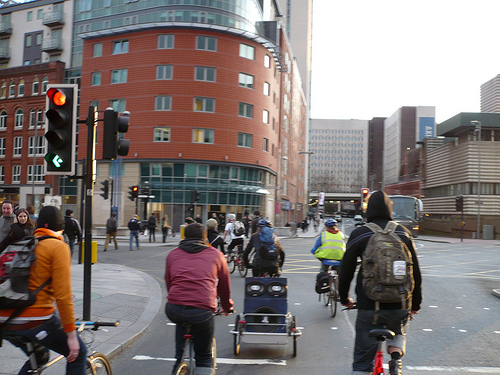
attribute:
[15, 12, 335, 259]
building — curved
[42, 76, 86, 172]
light — red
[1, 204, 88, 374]
person — riding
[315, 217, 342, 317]
person — riding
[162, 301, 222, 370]
blue jeans — blue 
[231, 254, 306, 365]
bicycle — pulling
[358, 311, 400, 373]
bicycle — riding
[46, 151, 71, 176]
arrow — turning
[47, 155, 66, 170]
arrow — green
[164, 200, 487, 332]
busy road — busy 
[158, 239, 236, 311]
jacket — red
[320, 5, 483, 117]
clear sky — bright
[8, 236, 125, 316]
jacket — orange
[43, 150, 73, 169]
arrow — green